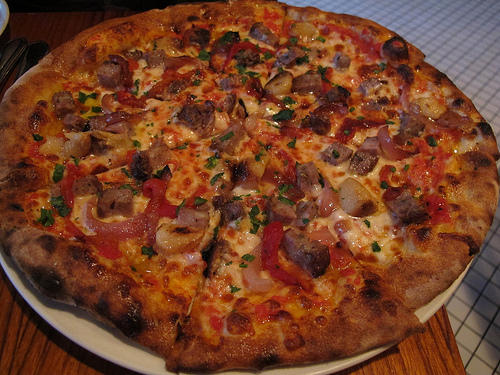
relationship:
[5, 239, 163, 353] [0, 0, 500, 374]
brown crust of cheese topping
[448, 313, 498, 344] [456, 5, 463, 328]
tiles on pizza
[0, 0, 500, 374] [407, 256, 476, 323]
cheese topping on a plate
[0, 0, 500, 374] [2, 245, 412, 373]
cheese topping on a plate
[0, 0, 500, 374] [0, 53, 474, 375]
cheese topping on plate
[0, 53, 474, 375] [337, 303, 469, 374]
plate sitting on a table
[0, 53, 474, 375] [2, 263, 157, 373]
plate sitting on a table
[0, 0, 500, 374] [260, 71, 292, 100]
cheese topping with meat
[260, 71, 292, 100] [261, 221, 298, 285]
meat and pepper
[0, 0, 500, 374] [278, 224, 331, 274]
cheese topping with sausage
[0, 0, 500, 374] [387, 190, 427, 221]
cheese topping with sausage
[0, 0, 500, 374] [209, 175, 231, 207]
cheese topping with sausage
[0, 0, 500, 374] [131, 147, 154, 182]
cheese topping with sausage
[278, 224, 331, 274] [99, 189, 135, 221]
sausage and vegetable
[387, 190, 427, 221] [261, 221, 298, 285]
sausage and pepper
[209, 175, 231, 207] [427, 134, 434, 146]
sausage and vegetable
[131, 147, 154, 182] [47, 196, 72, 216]
sausage and vegetable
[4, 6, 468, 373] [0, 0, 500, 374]
table to hold cheese topping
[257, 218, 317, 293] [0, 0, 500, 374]
pepper on cheese topping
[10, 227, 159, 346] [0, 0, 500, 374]
burned of cheese topping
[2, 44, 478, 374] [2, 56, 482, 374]
edge of plate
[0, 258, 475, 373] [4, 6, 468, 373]
plate on table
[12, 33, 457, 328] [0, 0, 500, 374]
cheese topping on cheese topping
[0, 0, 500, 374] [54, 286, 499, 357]
cheese topping on plate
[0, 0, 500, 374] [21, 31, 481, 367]
cheese topping on plate